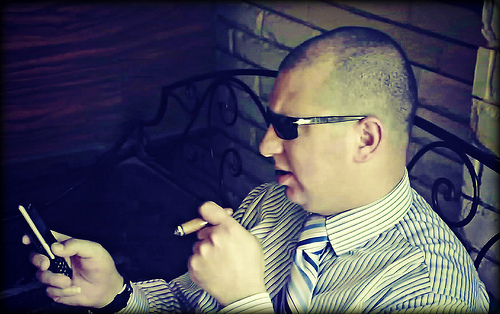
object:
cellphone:
[10, 195, 75, 285]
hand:
[20, 228, 127, 311]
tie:
[273, 215, 347, 314]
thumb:
[50, 238, 81, 259]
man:
[20, 25, 498, 314]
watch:
[94, 274, 141, 314]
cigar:
[172, 207, 234, 237]